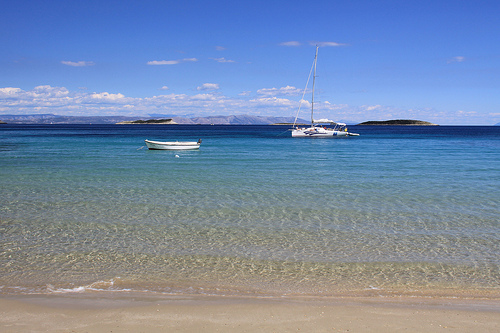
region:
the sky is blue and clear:
[22, 11, 170, 45]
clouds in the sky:
[8, 91, 149, 108]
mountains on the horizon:
[0, 108, 287, 133]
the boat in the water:
[134, 123, 218, 160]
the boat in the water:
[289, 44, 363, 139]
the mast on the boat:
[310, 40, 324, 135]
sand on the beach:
[6, 299, 494, 330]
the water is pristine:
[24, 190, 478, 280]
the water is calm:
[25, 151, 498, 281]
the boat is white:
[133, 133, 215, 161]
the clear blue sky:
[9, 3, 492, 33]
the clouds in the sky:
[10, 88, 288, 109]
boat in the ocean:
[135, 138, 208, 161]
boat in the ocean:
[285, 40, 373, 143]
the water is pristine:
[25, 172, 448, 244]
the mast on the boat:
[285, 39, 326, 128]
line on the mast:
[290, 60, 310, 131]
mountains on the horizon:
[4, 106, 305, 122]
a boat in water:
[138, 115, 252, 197]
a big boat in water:
[254, 47, 386, 183]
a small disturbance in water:
[39, 260, 151, 305]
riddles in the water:
[45, 194, 442, 288]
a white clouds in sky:
[43, 59, 438, 114]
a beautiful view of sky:
[26, 8, 497, 86]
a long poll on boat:
[293, 50, 336, 125]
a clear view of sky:
[11, 13, 491, 115]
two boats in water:
[85, 79, 405, 202]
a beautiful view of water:
[23, 131, 497, 212]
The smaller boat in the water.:
[143, 136, 203, 151]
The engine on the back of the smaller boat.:
[192, 136, 201, 143]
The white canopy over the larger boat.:
[315, 115, 349, 124]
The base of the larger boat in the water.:
[287, 130, 355, 134]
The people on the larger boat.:
[292, 124, 348, 130]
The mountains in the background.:
[12, 110, 346, 127]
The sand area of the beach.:
[2, 294, 497, 330]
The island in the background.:
[352, 116, 433, 126]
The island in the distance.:
[118, 118, 183, 120]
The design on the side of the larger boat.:
[300, 129, 331, 138]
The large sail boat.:
[297, 41, 355, 138]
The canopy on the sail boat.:
[312, 116, 347, 126]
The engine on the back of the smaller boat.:
[198, 138, 201, 141]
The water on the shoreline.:
[12, 180, 495, 301]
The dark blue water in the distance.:
[14, 120, 489, 143]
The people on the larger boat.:
[299, 123, 351, 135]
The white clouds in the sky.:
[7, 88, 493, 125]